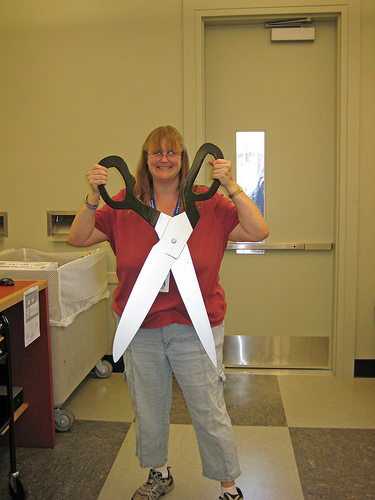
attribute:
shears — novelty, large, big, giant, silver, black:
[72, 144, 245, 375]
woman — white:
[67, 128, 278, 497]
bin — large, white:
[4, 240, 124, 401]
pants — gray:
[115, 312, 257, 484]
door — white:
[196, 18, 346, 383]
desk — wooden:
[0, 284, 62, 453]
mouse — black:
[0, 276, 18, 288]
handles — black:
[181, 141, 228, 229]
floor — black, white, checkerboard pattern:
[45, 365, 373, 499]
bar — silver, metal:
[227, 240, 336, 261]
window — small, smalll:
[231, 123, 269, 226]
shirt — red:
[98, 181, 234, 327]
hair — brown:
[149, 124, 181, 151]